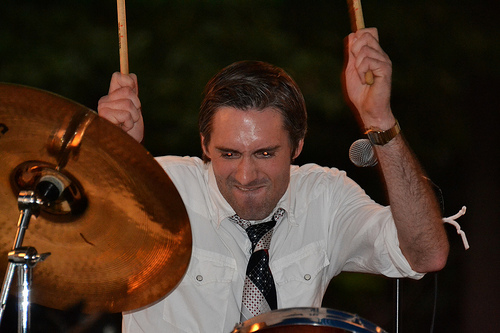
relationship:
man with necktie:
[153, 46, 344, 331] [236, 211, 281, 315]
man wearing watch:
[153, 46, 344, 331] [359, 114, 403, 150]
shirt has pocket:
[151, 148, 381, 332] [269, 241, 338, 332]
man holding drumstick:
[153, 46, 344, 331] [102, 2, 142, 100]